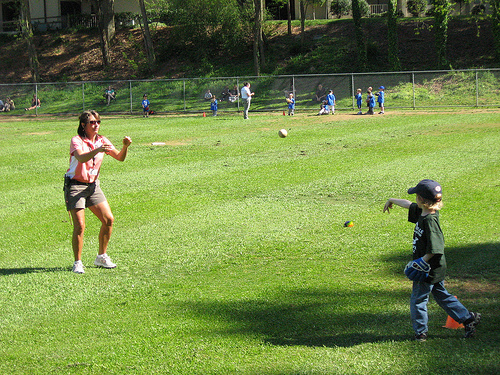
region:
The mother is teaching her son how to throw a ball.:
[60, 102, 475, 340]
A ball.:
[271, 121, 291, 142]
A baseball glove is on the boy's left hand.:
[390, 255, 430, 285]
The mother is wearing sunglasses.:
[50, 105, 110, 140]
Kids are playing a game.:
[125, 75, 390, 115]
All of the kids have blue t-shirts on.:
[135, 80, 395, 120]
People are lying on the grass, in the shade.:
[1, 76, 47, 121]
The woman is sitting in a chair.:
[95, 80, 115, 105]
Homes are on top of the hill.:
[10, 0, 446, 45]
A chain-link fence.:
[391, 67, 478, 108]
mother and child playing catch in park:
[36, 77, 484, 347]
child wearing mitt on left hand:
[361, 175, 481, 345]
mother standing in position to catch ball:
[50, 76, 150, 276]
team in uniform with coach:
[100, 75, 400, 130]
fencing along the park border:
[30, 45, 470, 125]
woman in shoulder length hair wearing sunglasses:
[56, 90, 136, 155]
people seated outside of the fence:
[5, 75, 127, 117]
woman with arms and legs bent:
[50, 101, 150, 276]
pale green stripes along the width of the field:
[45, 95, 467, 280]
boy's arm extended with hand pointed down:
[345, 187, 436, 222]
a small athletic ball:
[273, 124, 293, 141]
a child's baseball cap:
[403, 168, 452, 204]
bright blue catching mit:
[401, 245, 436, 285]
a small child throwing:
[377, 167, 497, 346]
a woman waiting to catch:
[31, 102, 142, 272]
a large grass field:
[0, 65, 482, 364]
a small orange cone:
[198, 106, 211, 117]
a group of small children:
[271, 85, 395, 129]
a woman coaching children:
[151, 67, 409, 120]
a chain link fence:
[26, 60, 461, 122]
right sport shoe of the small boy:
[465, 315, 477, 334]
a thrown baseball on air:
[277, 126, 296, 140]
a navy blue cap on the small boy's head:
[408, 177, 437, 196]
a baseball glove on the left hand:
[402, 260, 426, 275]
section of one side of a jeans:
[408, 282, 424, 324]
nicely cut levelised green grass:
[169, 214, 348, 344]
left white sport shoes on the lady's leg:
[95, 255, 115, 267]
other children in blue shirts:
[314, 80, 391, 109]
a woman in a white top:
[238, 74, 253, 119]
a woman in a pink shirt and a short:
[56, 102, 131, 272]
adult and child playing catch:
[48, 106, 484, 349]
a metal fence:
[4, 68, 497, 119]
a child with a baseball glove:
[378, 175, 460, 302]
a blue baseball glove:
[405, 252, 437, 279]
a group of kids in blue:
[288, 83, 392, 119]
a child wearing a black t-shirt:
[380, 175, 454, 297]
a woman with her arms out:
[73, 102, 138, 178]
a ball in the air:
[263, 122, 301, 143]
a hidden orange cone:
[444, 287, 464, 334]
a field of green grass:
[14, 117, 484, 346]